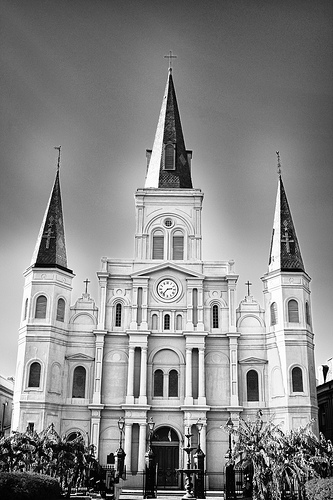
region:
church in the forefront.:
[0, 15, 331, 496]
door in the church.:
[143, 422, 185, 490]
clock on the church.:
[151, 273, 183, 302]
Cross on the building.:
[79, 273, 91, 293]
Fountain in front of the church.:
[176, 425, 198, 498]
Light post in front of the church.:
[112, 413, 127, 452]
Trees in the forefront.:
[217, 405, 331, 497]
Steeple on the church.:
[133, 48, 202, 187]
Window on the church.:
[159, 138, 177, 170]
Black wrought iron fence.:
[225, 465, 248, 494]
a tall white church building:
[29, 53, 309, 444]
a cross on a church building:
[146, 43, 184, 68]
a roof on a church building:
[141, 64, 198, 189]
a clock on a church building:
[144, 272, 186, 310]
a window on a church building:
[26, 347, 48, 389]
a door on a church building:
[146, 421, 185, 485]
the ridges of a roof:
[264, 268, 308, 285]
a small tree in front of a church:
[240, 422, 303, 499]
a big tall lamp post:
[139, 417, 157, 494]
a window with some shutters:
[147, 222, 188, 264]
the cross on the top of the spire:
[159, 46, 178, 68]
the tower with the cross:
[135, 44, 200, 191]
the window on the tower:
[159, 138, 178, 172]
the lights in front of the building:
[112, 413, 236, 440]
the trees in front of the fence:
[232, 411, 331, 499]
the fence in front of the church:
[87, 448, 125, 497]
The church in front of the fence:
[9, 34, 320, 441]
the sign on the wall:
[102, 447, 115, 465]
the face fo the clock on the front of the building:
[150, 275, 185, 305]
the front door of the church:
[143, 418, 183, 491]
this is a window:
[23, 363, 46, 394]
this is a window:
[65, 367, 87, 400]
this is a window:
[149, 366, 167, 399]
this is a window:
[163, 368, 181, 397]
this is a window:
[247, 367, 266, 406]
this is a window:
[288, 366, 304, 395]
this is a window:
[30, 296, 48, 325]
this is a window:
[111, 296, 126, 328]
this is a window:
[162, 309, 173, 328]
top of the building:
[138, 44, 202, 193]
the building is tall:
[4, 261, 316, 483]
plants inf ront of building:
[243, 421, 309, 496]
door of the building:
[142, 425, 176, 478]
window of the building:
[141, 354, 181, 402]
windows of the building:
[277, 290, 296, 324]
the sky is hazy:
[204, 145, 300, 229]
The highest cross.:
[163, 50, 178, 68]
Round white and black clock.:
[155, 279, 178, 300]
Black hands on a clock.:
[162, 287, 171, 296]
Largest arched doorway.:
[148, 423, 183, 491]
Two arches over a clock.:
[149, 227, 188, 261]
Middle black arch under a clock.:
[164, 313, 171, 330]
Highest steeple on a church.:
[143, 65, 192, 188]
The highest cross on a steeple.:
[164, 50, 177, 68]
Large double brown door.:
[149, 444, 178, 485]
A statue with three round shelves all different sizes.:
[176, 425, 201, 499]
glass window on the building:
[70, 366, 87, 399]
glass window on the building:
[27, 360, 38, 386]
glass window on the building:
[153, 368, 162, 396]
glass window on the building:
[167, 370, 175, 394]